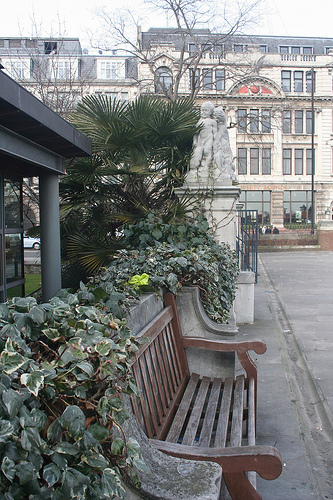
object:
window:
[152, 62, 176, 96]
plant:
[67, 81, 192, 249]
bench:
[97, 292, 284, 487]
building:
[0, 12, 331, 284]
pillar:
[28, 173, 69, 297]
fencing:
[233, 210, 261, 275]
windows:
[292, 68, 305, 93]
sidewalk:
[258, 239, 331, 496]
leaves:
[137, 265, 142, 274]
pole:
[303, 64, 322, 247]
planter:
[0, 237, 236, 335]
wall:
[230, 277, 258, 328]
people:
[259, 218, 280, 243]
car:
[17, 231, 42, 254]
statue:
[184, 101, 240, 219]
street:
[250, 249, 332, 500]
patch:
[284, 259, 322, 308]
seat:
[177, 369, 259, 444]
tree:
[92, 0, 293, 240]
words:
[185, 33, 322, 62]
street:
[13, 240, 102, 256]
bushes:
[0, 277, 129, 496]